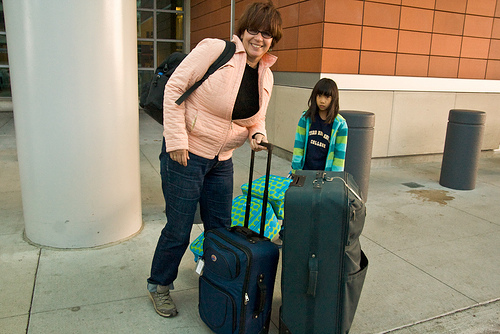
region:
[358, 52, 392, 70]
tile on back wall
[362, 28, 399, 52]
tile on back wall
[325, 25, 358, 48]
tile on back wall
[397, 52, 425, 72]
tile on back wall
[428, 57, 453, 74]
tile on back wall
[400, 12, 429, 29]
tile on back wall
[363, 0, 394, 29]
tile on back wall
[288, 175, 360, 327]
green suitcase standing upright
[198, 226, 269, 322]
blue suitcase standing upright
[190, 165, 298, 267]
green and blue polka dot luggage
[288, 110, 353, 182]
green and blue striped sweater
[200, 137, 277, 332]
luggage with a pull out handle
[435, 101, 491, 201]
cement pillars on the sidewalk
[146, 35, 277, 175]
peach colored zip up jacket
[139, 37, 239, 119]
black bag over the woman's right shoulder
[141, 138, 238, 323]
blue jeans with the legs rolled up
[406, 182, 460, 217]
stain from something spilled on the sidewalk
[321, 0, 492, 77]
brown blocks on the building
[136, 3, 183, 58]
square framed window glass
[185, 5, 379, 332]
woman posing with daughter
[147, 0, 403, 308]
woman posing with daughter before flight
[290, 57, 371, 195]
girl caught in photo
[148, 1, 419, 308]
woman with daughter outside of airport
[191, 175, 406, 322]
pieces of luggage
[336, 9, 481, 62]
tile wall on airport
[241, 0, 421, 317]
girl posing with mom and luggage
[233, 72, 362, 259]
girl posing with luggage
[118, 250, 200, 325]
right shoe of woman posing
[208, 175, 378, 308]
two pieces of carry on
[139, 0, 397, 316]
woman and girl standing with luggage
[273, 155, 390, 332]
large green suitcase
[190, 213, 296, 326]
navy blue and black suitcase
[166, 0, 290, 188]
woman wearing a peach jacket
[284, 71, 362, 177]
girl wearing a turquoise and green striped jacket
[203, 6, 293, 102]
woman wearing black rimmed glasses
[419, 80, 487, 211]
grey metal trashcan in front of a building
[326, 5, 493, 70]
orange bricks on a building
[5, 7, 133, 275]
white column in front of a building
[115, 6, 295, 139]
woman wearing a black backpack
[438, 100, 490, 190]
a short black pole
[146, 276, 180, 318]
the shoe of a woman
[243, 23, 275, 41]
a woman's black glasses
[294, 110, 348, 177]
a girl's long sleeve sweater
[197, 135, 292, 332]
a blue and black suitcase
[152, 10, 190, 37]
the window of a building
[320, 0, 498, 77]
part of a building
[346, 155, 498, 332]
part of a concrete sidewalk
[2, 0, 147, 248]
part of a large white pole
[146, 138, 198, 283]
the leg of a woman